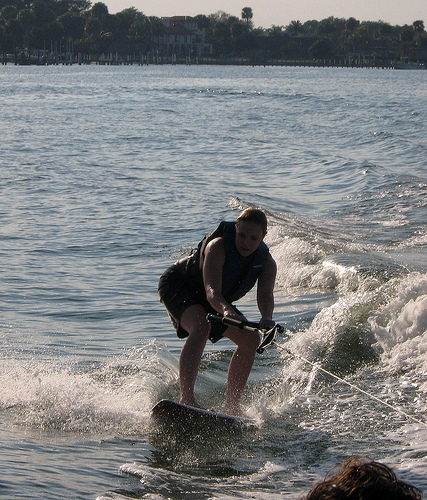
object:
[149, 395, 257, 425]
board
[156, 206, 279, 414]
person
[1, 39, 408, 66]
poles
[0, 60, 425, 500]
water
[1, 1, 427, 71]
leaves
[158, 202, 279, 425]
woman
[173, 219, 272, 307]
vest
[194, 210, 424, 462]
wave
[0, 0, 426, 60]
trees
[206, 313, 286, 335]
handle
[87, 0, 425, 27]
sky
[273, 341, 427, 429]
wire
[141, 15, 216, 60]
building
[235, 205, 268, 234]
hair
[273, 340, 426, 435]
string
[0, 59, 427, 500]
lake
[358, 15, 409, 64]
tree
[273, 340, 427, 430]
rope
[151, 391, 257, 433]
jet ski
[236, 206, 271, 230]
hair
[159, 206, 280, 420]
woman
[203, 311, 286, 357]
handlebar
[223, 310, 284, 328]
hands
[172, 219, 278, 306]
vest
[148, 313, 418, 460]
jet ski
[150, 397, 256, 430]
wakeboard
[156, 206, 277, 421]
person